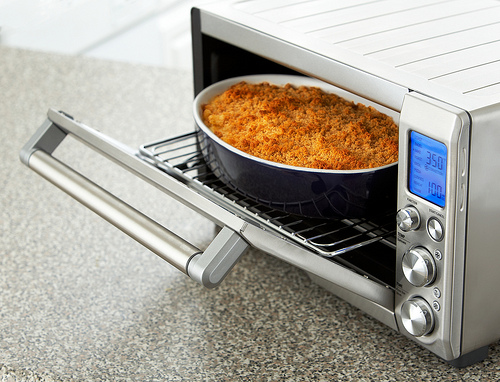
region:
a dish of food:
[183, 87, 425, 186]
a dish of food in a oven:
[102, 77, 429, 268]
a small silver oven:
[15, 94, 462, 284]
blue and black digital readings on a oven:
[402, 129, 452, 205]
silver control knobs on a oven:
[388, 205, 443, 360]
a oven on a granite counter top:
[41, 95, 478, 355]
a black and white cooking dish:
[155, 112, 395, 194]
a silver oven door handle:
[0, 104, 263, 280]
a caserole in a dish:
[178, 80, 380, 195]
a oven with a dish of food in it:
[22, 32, 469, 314]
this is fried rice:
[236, 87, 348, 141]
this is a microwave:
[410, 95, 492, 338]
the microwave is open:
[217, 99, 414, 237]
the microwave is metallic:
[401, 220, 463, 332]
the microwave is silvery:
[395, 216, 465, 339]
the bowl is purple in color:
[277, 174, 329, 194]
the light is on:
[408, 146, 444, 188]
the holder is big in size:
[111, 206, 191, 261]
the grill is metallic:
[317, 225, 367, 255]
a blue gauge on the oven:
[404, 129, 445, 204]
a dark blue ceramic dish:
[268, 167, 333, 211]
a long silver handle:
[48, 157, 118, 206]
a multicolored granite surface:
[85, 320, 162, 369]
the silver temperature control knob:
[394, 202, 421, 229]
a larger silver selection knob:
[402, 245, 438, 287]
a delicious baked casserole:
[266, 95, 349, 153]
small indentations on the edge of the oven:
[459, 144, 470, 211]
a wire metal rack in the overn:
[312, 234, 343, 251]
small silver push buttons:
[429, 285, 442, 311]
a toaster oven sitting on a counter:
[32, 10, 474, 334]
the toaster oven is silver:
[60, 7, 497, 368]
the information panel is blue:
[400, 129, 451, 211]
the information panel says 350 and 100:
[404, 122, 453, 213]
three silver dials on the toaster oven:
[387, 201, 443, 346]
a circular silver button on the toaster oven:
[419, 210, 456, 248]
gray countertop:
[26, 219, 292, 354]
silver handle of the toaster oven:
[18, 126, 233, 280]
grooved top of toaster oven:
[223, 5, 472, 109]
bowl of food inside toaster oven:
[181, 90, 388, 216]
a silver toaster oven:
[58, 25, 446, 335]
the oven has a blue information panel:
[407, 130, 449, 207]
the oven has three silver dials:
[398, 193, 438, 345]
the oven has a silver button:
[423, 210, 453, 243]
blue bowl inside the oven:
[189, 76, 391, 246]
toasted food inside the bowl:
[221, 83, 386, 182]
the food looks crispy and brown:
[217, 90, 375, 175]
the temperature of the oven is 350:
[423, 149, 459, 181]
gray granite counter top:
[6, 184, 363, 377]